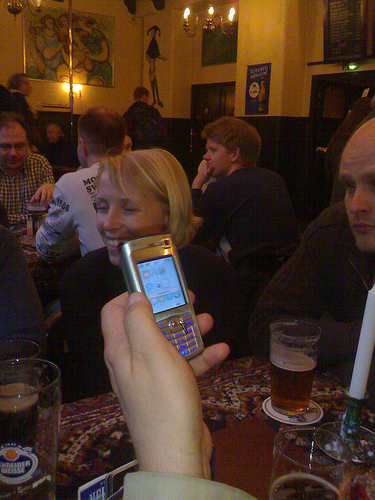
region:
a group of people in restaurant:
[12, 14, 353, 476]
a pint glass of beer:
[245, 295, 338, 435]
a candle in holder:
[328, 270, 373, 471]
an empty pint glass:
[0, 342, 72, 498]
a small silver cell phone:
[107, 228, 238, 373]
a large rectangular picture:
[8, 0, 136, 96]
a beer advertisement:
[231, 53, 280, 122]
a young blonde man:
[171, 106, 298, 267]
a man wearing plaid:
[0, 96, 60, 239]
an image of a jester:
[138, 16, 176, 117]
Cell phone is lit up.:
[116, 230, 208, 367]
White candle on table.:
[342, 277, 374, 450]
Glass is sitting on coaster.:
[257, 385, 325, 427]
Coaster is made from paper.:
[260, 388, 325, 429]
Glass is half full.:
[265, 315, 322, 418]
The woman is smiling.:
[93, 143, 195, 273]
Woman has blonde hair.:
[81, 144, 203, 261]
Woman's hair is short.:
[83, 145, 207, 262]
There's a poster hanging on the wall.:
[237, 58, 279, 116]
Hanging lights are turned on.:
[177, 0, 244, 39]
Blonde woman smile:
[30, 133, 257, 412]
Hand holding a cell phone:
[87, 222, 252, 498]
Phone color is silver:
[113, 225, 215, 368]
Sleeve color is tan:
[101, 458, 266, 498]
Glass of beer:
[256, 307, 328, 421]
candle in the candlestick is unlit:
[318, 272, 373, 471]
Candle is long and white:
[331, 276, 372, 405]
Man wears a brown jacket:
[241, 186, 371, 413]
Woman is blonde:
[27, 146, 257, 396]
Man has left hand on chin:
[175, 107, 305, 316]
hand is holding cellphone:
[80, 292, 238, 477]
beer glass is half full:
[250, 315, 328, 428]